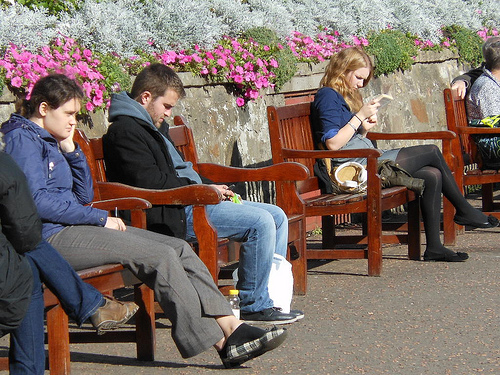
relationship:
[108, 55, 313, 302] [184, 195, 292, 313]
man wearing blue jeans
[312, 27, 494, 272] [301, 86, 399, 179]
woman wearing a dress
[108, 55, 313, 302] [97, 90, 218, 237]
man wearing jacket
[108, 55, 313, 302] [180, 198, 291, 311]
man wearing jeans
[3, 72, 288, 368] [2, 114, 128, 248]
woman wearing blue jacket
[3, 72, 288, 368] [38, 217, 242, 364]
woman wearing pants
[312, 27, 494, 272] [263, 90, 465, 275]
woman sitting on bench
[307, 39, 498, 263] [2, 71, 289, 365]
girl sitting on girl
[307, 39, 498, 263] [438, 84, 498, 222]
girl sitting on bench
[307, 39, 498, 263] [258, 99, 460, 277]
girl sitting on bench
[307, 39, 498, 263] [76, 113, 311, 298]
girl sitting on bench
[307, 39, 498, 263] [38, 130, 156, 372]
girl sitting on bench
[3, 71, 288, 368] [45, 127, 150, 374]
lady sitting on chair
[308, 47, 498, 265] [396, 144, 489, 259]
lady wearing tights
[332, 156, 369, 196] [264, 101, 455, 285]
headphones on bench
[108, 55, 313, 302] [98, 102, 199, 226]
man wearing jacket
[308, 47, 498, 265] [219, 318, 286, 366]
lady wearing shoes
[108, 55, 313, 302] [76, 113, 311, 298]
man sitting on a bench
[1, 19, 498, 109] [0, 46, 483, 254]
flowers on a wall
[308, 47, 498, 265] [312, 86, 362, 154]
lady wearing jacket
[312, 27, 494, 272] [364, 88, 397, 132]
woman reading a book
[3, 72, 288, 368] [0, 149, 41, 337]
woman wearing jacket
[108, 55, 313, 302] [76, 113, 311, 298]
man seated on bench